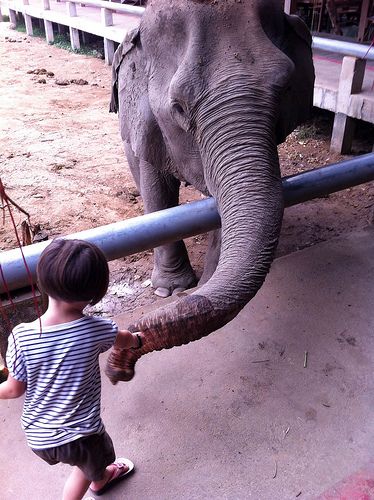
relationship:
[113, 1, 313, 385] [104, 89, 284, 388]
elephant has elephant trunk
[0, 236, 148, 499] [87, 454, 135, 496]
child wearing sandal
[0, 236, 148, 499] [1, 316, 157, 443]
child wearing stripped shirt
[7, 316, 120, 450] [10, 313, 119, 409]
stripes on child's shirt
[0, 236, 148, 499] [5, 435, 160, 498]
child wearing grey shorts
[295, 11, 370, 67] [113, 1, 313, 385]
long grey tube surrounding elephant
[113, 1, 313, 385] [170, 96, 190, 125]
elephant has eye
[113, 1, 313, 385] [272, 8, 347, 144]
elephant has ear of elephant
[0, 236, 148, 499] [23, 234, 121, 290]
child has "short hair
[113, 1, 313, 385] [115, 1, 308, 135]
elephant has grey elphant face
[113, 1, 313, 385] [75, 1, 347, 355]
elephant in an enclosure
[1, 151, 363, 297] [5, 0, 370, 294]
bar around enclosure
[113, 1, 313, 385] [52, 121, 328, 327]
elephant walks on dirt surface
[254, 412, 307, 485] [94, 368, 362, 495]
twigs on ground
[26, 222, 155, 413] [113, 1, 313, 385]
child playing playing with elephant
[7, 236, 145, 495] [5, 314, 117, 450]
child wearing shirt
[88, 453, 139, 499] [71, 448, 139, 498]
child wearing sandal on child's foot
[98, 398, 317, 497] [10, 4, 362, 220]
concrete area outside enclosure